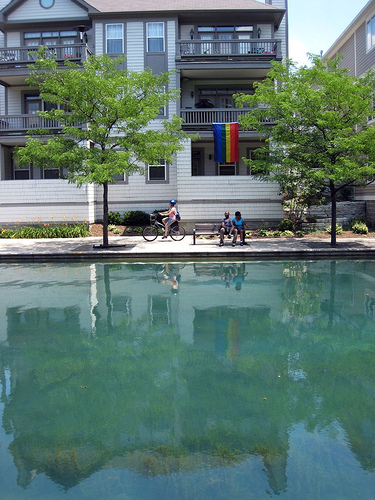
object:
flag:
[212, 121, 240, 166]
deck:
[179, 106, 275, 128]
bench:
[191, 223, 246, 247]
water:
[0, 258, 375, 500]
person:
[158, 197, 179, 239]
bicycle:
[140, 210, 185, 242]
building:
[0, 0, 293, 226]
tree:
[13, 42, 201, 248]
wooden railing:
[179, 107, 279, 125]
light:
[189, 29, 195, 40]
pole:
[191, 41, 193, 54]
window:
[145, 35, 164, 51]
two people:
[218, 209, 244, 247]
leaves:
[127, 101, 130, 109]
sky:
[287, 0, 375, 78]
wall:
[94, 22, 177, 225]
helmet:
[169, 199, 177, 204]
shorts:
[163, 218, 175, 228]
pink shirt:
[167, 207, 179, 221]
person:
[231, 210, 249, 247]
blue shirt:
[231, 215, 244, 230]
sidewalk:
[0, 233, 375, 253]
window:
[105, 23, 124, 41]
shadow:
[0, 224, 127, 256]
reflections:
[149, 261, 183, 296]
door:
[215, 27, 234, 54]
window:
[146, 164, 168, 184]